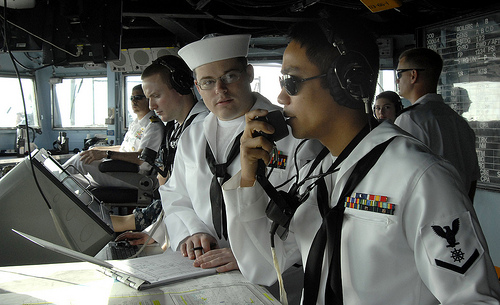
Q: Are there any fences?
A: No, there are no fences.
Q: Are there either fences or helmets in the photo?
A: No, there are no fences or helmets.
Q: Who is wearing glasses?
A: The man is wearing glasses.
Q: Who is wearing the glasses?
A: The man is wearing glasses.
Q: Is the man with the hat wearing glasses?
A: Yes, the man is wearing glasses.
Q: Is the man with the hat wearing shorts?
A: No, the man is wearing glasses.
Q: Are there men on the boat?
A: Yes, there is a man on the boat.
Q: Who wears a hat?
A: The man wears a hat.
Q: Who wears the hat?
A: The man wears a hat.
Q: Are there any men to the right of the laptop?
A: Yes, there is a man to the right of the laptop.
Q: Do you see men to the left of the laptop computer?
A: No, the man is to the right of the laptop computer.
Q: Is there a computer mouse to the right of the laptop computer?
A: No, there is a man to the right of the laptop computer.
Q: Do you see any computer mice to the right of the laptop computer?
A: No, there is a man to the right of the laptop computer.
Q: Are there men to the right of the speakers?
A: Yes, there is a man to the right of the speakers.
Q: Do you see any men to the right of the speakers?
A: Yes, there is a man to the right of the speakers.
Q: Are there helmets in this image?
A: No, there are no helmets.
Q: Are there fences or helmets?
A: No, there are no helmets or fences.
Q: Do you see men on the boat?
A: Yes, there is a man on the boat.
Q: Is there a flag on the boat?
A: No, there is a man on the boat.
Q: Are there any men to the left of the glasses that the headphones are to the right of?
A: Yes, there is a man to the left of the glasses.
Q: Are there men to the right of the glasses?
A: No, the man is to the left of the glasses.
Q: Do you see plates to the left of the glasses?
A: No, there is a man to the left of the glasses.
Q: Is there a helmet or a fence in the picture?
A: No, there are no helmets or fences.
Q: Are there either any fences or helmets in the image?
A: No, there are no helmets or fences.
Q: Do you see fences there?
A: No, there are no fences.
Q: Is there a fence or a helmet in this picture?
A: No, there are no fences or helmets.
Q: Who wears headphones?
A: The man wears headphones.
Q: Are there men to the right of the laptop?
A: Yes, there is a man to the right of the laptop.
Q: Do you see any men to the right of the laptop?
A: Yes, there is a man to the right of the laptop.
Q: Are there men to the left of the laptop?
A: No, the man is to the right of the laptop.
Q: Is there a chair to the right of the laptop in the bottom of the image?
A: No, there is a man to the right of the laptop.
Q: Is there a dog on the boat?
A: No, there is a man on the boat.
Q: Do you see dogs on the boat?
A: No, there is a man on the boat.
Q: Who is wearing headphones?
A: The man is wearing headphones.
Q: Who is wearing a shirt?
A: The man is wearing a shirt.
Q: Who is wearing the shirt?
A: The man is wearing a shirt.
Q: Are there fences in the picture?
A: No, there are no fences.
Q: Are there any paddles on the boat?
A: No, there is a man on the boat.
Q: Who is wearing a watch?
A: The man is wearing a watch.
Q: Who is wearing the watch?
A: The man is wearing a watch.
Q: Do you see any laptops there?
A: Yes, there is a laptop.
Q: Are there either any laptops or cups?
A: Yes, there is a laptop.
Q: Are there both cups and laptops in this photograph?
A: No, there is a laptop but no cups.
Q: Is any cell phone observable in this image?
A: No, there are no cell phones.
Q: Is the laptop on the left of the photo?
A: Yes, the laptop is on the left of the image.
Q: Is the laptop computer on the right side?
A: No, the laptop computer is on the left of the image.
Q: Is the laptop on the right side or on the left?
A: The laptop is on the left of the image.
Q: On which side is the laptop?
A: The laptop is on the left of the image.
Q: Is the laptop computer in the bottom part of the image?
A: Yes, the laptop computer is in the bottom of the image.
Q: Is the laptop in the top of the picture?
A: No, the laptop is in the bottom of the image.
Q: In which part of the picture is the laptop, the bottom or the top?
A: The laptop is in the bottom of the image.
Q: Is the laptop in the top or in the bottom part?
A: The laptop is in the bottom of the image.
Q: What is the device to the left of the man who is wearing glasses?
A: The device is a laptop.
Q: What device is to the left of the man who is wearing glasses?
A: The device is a laptop.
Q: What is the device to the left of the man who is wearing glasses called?
A: The device is a laptop.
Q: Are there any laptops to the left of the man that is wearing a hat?
A: Yes, there is a laptop to the left of the man.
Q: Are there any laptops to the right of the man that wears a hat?
A: No, the laptop is to the left of the man.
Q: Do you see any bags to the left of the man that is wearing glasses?
A: No, there is a laptop to the left of the man.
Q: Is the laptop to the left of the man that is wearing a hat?
A: Yes, the laptop is to the left of the man.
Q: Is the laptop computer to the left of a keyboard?
A: No, the laptop computer is to the left of the man.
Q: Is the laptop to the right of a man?
A: No, the laptop is to the left of a man.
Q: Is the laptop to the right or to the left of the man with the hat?
A: The laptop is to the left of the man.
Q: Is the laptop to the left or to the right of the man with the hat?
A: The laptop is to the left of the man.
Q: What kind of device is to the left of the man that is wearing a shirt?
A: The device is a laptop.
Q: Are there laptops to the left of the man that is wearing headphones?
A: Yes, there is a laptop to the left of the man.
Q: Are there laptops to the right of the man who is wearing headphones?
A: No, the laptop is to the left of the man.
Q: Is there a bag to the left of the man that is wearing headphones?
A: No, there is a laptop to the left of the man.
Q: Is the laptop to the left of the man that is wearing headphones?
A: Yes, the laptop is to the left of the man.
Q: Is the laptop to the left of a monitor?
A: No, the laptop is to the left of the man.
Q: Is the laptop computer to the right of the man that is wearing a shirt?
A: No, the laptop computer is to the left of the man.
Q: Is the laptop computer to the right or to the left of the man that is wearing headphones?
A: The laptop computer is to the left of the man.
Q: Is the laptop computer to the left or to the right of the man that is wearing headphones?
A: The laptop computer is to the left of the man.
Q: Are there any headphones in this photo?
A: Yes, there are headphones.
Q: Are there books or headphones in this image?
A: Yes, there are headphones.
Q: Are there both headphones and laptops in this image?
A: Yes, there are both headphones and a laptop.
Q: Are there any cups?
A: No, there are no cups.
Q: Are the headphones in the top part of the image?
A: Yes, the headphones are in the top of the image.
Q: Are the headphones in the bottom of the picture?
A: No, the headphones are in the top of the image.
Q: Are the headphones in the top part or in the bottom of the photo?
A: The headphones are in the top of the image.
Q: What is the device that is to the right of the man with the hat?
A: The device is headphones.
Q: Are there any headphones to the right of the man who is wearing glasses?
A: Yes, there are headphones to the right of the man.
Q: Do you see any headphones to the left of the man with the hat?
A: No, the headphones are to the right of the man.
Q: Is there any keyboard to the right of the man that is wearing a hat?
A: No, there are headphones to the right of the man.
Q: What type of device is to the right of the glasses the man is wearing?
A: The device is headphones.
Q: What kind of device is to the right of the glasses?
A: The device is headphones.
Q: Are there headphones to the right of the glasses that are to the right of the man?
A: Yes, there are headphones to the right of the glasses.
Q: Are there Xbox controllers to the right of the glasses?
A: No, there are headphones to the right of the glasses.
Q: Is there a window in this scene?
A: Yes, there is a window.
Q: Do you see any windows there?
A: Yes, there is a window.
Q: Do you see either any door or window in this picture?
A: Yes, there is a window.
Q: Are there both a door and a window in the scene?
A: No, there is a window but no doors.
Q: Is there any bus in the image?
A: No, there are no buses.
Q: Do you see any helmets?
A: No, there are no helmets.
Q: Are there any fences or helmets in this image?
A: No, there are no helmets or fences.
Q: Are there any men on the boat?
A: Yes, there is a man on the boat.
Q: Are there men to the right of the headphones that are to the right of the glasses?
A: Yes, there is a man to the right of the headphones.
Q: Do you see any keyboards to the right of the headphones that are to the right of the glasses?
A: No, there is a man to the right of the headphones.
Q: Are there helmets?
A: No, there are no helmets.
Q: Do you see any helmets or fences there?
A: No, there are no helmets or fences.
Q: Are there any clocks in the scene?
A: No, there are no clocks.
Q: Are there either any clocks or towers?
A: No, there are no clocks or towers.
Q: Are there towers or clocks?
A: No, there are no clocks or towers.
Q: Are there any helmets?
A: No, there are no helmets.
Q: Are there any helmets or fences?
A: No, there are no helmets or fences.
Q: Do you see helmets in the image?
A: No, there are no helmets.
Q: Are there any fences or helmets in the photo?
A: No, there are no helmets or fences.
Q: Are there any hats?
A: Yes, there is a hat.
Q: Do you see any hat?
A: Yes, there is a hat.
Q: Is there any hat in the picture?
A: Yes, there is a hat.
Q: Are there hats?
A: Yes, there is a hat.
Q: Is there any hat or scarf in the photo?
A: Yes, there is a hat.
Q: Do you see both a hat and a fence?
A: No, there is a hat but no fences.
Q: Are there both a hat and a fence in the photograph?
A: No, there is a hat but no fences.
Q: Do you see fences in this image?
A: No, there are no fences.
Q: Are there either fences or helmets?
A: No, there are no fences or helmets.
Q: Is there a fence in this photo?
A: No, there are no fences.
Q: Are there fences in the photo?
A: No, there are no fences.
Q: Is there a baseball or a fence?
A: No, there are no fences or baseballs.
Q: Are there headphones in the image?
A: Yes, there are headphones.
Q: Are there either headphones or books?
A: Yes, there are headphones.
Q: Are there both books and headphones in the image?
A: No, there are headphones but no books.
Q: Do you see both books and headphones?
A: No, there are headphones but no books.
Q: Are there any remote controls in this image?
A: No, there are no remote controls.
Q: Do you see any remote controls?
A: No, there are no remote controls.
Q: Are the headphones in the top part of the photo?
A: Yes, the headphones are in the top of the image.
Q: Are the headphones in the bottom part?
A: No, the headphones are in the top of the image.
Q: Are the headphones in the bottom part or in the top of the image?
A: The headphones are in the top of the image.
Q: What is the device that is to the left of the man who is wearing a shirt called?
A: The device is headphones.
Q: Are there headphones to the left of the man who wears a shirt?
A: Yes, there are headphones to the left of the man.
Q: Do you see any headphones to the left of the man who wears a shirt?
A: Yes, there are headphones to the left of the man.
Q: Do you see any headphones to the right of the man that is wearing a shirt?
A: No, the headphones are to the left of the man.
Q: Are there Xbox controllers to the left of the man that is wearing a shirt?
A: No, there are headphones to the left of the man.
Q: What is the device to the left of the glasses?
A: The device is headphones.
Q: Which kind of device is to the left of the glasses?
A: The device is headphones.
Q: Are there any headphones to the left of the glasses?
A: Yes, there are headphones to the left of the glasses.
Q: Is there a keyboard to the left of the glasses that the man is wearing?
A: No, there are headphones to the left of the glasses.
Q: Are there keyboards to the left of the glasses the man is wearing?
A: No, there are headphones to the left of the glasses.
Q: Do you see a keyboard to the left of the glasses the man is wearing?
A: No, there are headphones to the left of the glasses.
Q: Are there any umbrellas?
A: No, there are no umbrellas.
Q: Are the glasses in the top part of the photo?
A: Yes, the glasses are in the top of the image.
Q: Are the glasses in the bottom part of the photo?
A: No, the glasses are in the top of the image.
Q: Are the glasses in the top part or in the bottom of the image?
A: The glasses are in the top of the image.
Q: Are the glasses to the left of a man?
A: No, the glasses are to the right of a man.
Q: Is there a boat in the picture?
A: Yes, there is a boat.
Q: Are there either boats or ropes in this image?
A: Yes, there is a boat.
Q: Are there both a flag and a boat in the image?
A: No, there is a boat but no flags.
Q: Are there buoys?
A: No, there are no buoys.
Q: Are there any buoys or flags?
A: No, there are no buoys or flags.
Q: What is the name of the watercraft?
A: The watercraft is a boat.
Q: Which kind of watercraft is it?
A: The watercraft is a boat.